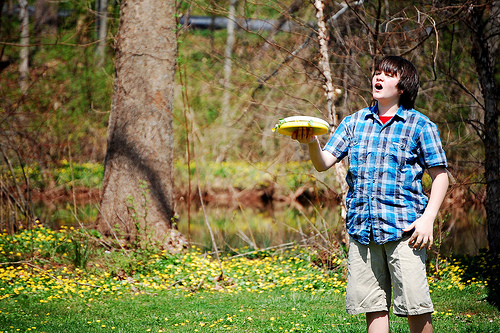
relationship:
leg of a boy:
[375, 237, 458, 331] [297, 67, 484, 262]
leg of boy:
[382, 237, 435, 332] [290, 55, 450, 332]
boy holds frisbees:
[290, 55, 450, 332] [273, 115, 330, 135]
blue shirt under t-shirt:
[322, 107, 447, 243] [376, 116, 392, 123]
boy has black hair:
[290, 55, 450, 332] [369, 54, 421, 111]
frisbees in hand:
[267, 112, 333, 139] [288, 130, 323, 147]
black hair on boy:
[369, 53, 421, 110] [284, 44, 460, 331]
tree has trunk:
[71, 46, 175, 181] [124, 53, 180, 234]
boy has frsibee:
[290, 55, 450, 332] [268, 103, 345, 134]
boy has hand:
[290, 55, 450, 332] [403, 218, 435, 251]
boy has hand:
[290, 55, 450, 332] [288, 127, 318, 146]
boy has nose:
[290, 55, 450, 332] [369, 72, 394, 90]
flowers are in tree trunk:
[4, 221, 62, 253] [90, 0, 180, 244]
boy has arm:
[301, 44, 474, 328] [371, 148, 481, 253]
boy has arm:
[290, 55, 450, 332] [291, 111, 356, 171]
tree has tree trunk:
[90, 0, 182, 250] [90, 0, 180, 244]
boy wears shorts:
[290, 55, 450, 332] [348, 236, 433, 318]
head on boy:
[358, 46, 427, 109] [290, 55, 450, 332]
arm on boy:
[293, 126, 346, 167] [290, 55, 450, 332]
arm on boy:
[403, 120, 451, 252] [290, 55, 450, 332]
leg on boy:
[344, 237, 389, 332] [290, 55, 450, 332]